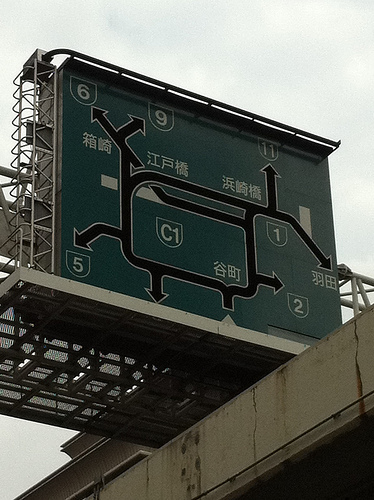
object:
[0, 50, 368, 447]
structure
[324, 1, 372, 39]
clouds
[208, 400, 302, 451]
wall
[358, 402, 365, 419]
rust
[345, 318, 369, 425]
crack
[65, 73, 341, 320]
traffic sign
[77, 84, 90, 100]
6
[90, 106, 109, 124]
arrows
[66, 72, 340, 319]
characters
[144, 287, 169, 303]
arrow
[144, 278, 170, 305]
down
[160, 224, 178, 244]
c1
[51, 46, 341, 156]
bar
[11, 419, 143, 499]
building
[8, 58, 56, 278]
rafters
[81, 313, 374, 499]
bridge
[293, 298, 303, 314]
number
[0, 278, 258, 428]
grate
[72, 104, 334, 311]
arrow map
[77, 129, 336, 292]
foreign writing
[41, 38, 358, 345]
sign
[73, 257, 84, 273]
number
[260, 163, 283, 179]
arrow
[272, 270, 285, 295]
arrow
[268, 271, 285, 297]
right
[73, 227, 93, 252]
arrow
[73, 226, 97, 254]
left